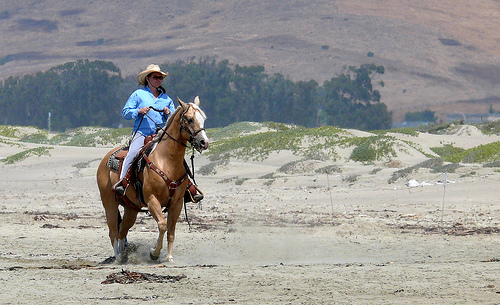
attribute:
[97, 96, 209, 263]
horse — brown, beautiful, lovely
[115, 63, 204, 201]
woman — riding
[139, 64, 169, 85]
hat — straw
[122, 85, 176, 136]
shirt — blue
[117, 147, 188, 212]
harness — red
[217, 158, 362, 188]
pile — sandy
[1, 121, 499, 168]
plants — growing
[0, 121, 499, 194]
dunes — sandy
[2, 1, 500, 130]
sky — blue, cloudy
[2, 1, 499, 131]
clouds — white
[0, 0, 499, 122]
mountain — treeless